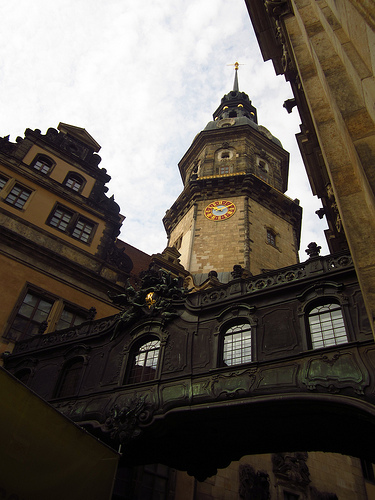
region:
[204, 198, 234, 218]
a large clock on the side of the building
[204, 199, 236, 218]
an orange clock on the side of the tower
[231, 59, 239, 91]
pointed top of tower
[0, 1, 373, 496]
large brown buildings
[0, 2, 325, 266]
part of sky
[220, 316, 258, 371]
a window on a building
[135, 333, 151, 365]
a window on a building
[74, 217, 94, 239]
a window on a building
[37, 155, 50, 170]
a window on a building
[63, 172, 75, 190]
a window on a building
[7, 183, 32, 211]
a window on a building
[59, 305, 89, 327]
a window on a building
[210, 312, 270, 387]
This is a window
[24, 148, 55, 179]
This is a window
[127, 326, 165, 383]
This is a window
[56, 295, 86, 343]
This is a window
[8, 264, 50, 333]
This is a window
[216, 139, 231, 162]
This is a window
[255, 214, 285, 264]
This is a window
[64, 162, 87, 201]
This is a window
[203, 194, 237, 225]
red and white clock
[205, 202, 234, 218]
clock is red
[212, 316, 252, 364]
window in the building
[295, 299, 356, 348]
a window in the building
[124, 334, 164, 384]
window is in the building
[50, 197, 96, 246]
windows on the side of the building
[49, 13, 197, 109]
the sky up above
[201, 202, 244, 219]
a clock that is gold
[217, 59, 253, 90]
the top of the building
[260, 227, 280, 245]
a window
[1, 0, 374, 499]
the building is large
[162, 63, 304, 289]
the tower is tall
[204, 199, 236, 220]
the clock is red and gold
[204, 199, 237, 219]
the hands on the clock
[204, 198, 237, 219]
the clock hands are solid gold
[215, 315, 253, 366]
the arched windows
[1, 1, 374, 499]
the building has windows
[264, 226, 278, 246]
the window is small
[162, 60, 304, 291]
the tower has windows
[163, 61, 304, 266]
the point at the top of the tower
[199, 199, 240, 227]
The clock has red roman numerals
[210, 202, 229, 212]
The hands of the clock are yellow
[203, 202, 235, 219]
The face of the clock is white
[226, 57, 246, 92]
steeple on a church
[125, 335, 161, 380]
window on a building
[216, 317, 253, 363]
window on a building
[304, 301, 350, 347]
window on a building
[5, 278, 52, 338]
window on a building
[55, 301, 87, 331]
window on a building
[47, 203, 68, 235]
window on a building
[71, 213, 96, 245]
window on a building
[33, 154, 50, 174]
window on a building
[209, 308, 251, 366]
A window on a building.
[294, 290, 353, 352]
A window on a building.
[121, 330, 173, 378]
A window on a building.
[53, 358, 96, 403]
A window on a building.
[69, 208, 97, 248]
A window on a building.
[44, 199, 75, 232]
A window on a building.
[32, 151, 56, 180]
A window on a building.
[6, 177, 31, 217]
A window on a building.